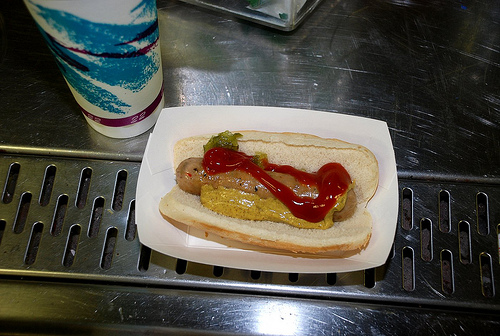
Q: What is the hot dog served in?
A: A paper bowl.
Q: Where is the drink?
A: To the left of the hot dog.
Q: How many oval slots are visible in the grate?
A: Twenty-six.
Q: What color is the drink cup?
A: White blue, and purple.